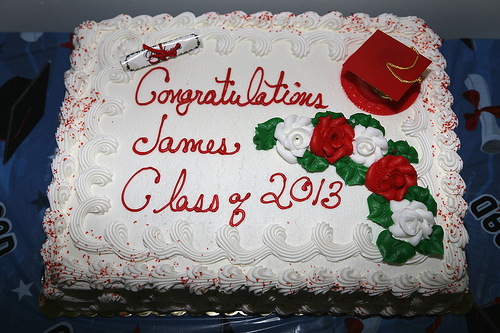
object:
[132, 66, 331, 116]
writing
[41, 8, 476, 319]
cake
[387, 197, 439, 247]
flowers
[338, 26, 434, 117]
hat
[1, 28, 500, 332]
cloth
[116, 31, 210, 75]
diploma